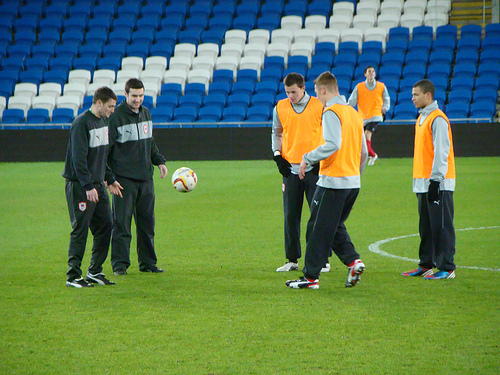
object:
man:
[104, 77, 168, 277]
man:
[62, 85, 125, 288]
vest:
[277, 95, 327, 164]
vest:
[319, 104, 364, 178]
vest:
[413, 108, 456, 179]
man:
[402, 79, 456, 280]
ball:
[171, 167, 197, 193]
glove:
[273, 155, 293, 179]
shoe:
[424, 269, 456, 280]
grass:
[193, 191, 273, 249]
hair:
[413, 79, 435, 99]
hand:
[159, 164, 168, 179]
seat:
[213, 68, 233, 83]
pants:
[111, 175, 157, 272]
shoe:
[285, 276, 320, 290]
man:
[270, 72, 332, 272]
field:
[1, 157, 499, 374]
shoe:
[139, 267, 165, 272]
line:
[366, 226, 499, 271]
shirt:
[62, 109, 117, 191]